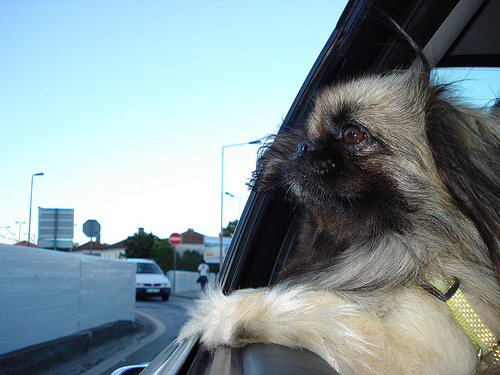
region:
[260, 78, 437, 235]
the head of the dog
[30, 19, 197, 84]
the blue sky in the background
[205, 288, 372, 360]
one leg of the dog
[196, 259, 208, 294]
a girl walking out of focus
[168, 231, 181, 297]
an illegible traffic sign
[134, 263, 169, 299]
the front view of the car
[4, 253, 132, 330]
a white wall on the street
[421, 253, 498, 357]
the collar of the dog is yellow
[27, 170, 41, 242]
a tall lamp in the distance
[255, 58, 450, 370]
brown and black dog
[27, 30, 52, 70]
white clouds n blue sky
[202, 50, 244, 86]
white clouds n blue sky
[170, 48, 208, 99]
white clouds n blue sky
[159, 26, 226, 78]
white clouds n blue sky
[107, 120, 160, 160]
white clouds n blue sky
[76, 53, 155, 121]
white clouds n blue sky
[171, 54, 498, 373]
Pekingese on a joy ride in master's car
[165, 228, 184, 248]
this sign is universal language for "stop"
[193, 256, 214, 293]
a pedestrian with jacket tied around his waist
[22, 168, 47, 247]
street light in the distance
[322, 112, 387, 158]
Pekingese eye is a big bulgy brown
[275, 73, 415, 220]
Pekingese face looks like it's been squashed in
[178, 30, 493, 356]
a tan and black dog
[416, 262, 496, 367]
a yellow leash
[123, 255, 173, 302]
a white van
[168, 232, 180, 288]
a red stop sign on a metal pole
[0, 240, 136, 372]
a concrete wall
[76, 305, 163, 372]
a yellow line on the side of the road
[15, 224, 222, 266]
brown roofed houses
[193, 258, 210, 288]
a person walking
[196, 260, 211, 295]
a person wearing a white shirt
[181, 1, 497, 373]
a dog looking out an open window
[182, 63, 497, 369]
small dog leaning out of car window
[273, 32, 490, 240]
black face on gray dog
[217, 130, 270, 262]
silver light pole with street lamp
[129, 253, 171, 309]
white van appraoching on road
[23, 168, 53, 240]
silver light pole with lamp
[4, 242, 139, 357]
white concrete wall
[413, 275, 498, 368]
yellow leash on dog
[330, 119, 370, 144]
brown eyes on dog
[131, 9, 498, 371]
open car window with dog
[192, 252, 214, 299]
person in white shirt with bag over shoulder walking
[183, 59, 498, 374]
dog leaning out window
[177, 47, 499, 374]
dog is black and white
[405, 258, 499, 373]
strap on dog's back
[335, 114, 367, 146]
dog's eye is brown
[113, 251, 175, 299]
white van behind car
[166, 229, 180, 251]
red and white sign on pole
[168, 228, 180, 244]
red and white sign is round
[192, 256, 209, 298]
man walking alongside road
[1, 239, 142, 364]
short white wall by road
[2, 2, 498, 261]
sky is turning to dusk color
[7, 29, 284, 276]
a blue sky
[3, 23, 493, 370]
a scene during the day time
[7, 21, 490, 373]
a scene outside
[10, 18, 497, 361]
a scene of the street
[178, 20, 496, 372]
a dog looking out of a car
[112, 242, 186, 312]
a white van in the background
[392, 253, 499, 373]
a yellow collar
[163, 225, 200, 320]
a red and white sign